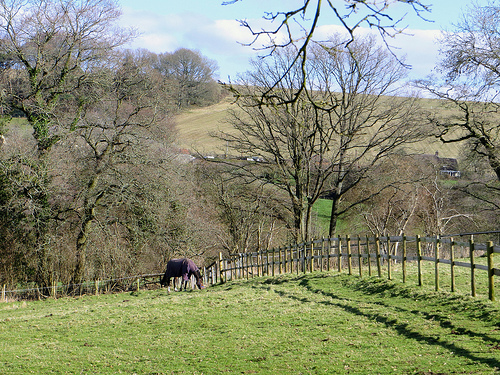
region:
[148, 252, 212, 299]
horse in a blanket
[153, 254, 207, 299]
horse is chowing down on green grass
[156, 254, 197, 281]
horse's blanket is a good rich purple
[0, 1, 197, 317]
it's cold, but not winter yet. there are still some leaves.....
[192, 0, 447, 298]
.....but not on all the trees, these two have only a few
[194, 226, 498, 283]
a river or canal in the middle distance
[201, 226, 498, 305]
long wooden fence, not quite pickets but poles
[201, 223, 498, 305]
poles are yellow, or perhaps just a plain wood colour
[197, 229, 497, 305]
slats are white. gate, i think, at the far end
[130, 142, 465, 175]
buildings in the not too far distance, over the river & the velvety green grass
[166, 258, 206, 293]
A horse in a field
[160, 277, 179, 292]
The back legs of the horse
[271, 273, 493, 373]
A shadow in the field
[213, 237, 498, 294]
A fence in the field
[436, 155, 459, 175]
A house behind the trees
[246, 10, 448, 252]
Trees behind the fence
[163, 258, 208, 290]
The horse is eating grass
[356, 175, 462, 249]
The trees have no leaves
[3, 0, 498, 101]
Blue sky above the horse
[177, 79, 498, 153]
A field behind the house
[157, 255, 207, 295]
brown livestock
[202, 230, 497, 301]
a brown wooden fence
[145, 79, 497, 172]
a farm field in the background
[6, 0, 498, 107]
blue sky with white clouds in it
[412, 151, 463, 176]
white house with a brown roof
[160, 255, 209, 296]
brown horse grazing on grass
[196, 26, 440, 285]
three bare trees growing close together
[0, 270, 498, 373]
short green grass in the horse's pasture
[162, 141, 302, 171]
several buildings in the background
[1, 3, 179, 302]
two twisted, bare trees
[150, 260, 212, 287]
horse is in field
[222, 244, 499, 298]
fence surrounds the grounds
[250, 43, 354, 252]
trees are bare in photo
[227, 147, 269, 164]
house is in distance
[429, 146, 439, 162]
chimney of house in picture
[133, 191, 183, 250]
branches from the trees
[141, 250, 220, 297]
horse is gray in color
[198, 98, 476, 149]
mountain side of landscape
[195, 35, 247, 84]
clouds in the sky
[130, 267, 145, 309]
post of fence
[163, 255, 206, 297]
this is a horse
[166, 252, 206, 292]
the horse is feeding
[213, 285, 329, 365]
this is the grass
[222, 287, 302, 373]
the grass is green in color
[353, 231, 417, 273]
this is a fence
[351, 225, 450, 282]
the fence is wooden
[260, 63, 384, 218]
this is a tree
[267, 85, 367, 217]
the tree is dry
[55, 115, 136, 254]
the tree is branchy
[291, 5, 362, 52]
the branches are thin